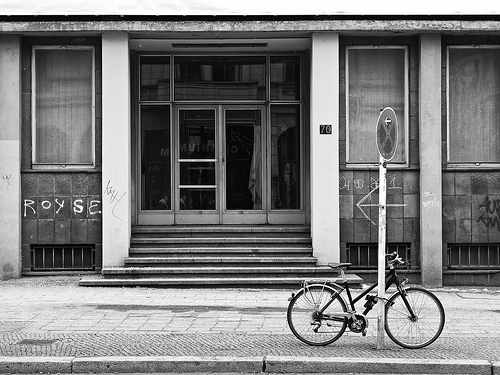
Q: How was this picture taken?
A: A camera.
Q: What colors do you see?
A: Black and white.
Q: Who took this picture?
A: A photographer.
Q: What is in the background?
A: Building.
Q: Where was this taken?
A: Street.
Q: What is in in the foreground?
A: Bike.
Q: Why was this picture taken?
A: Art.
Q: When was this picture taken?
A: Daytime.